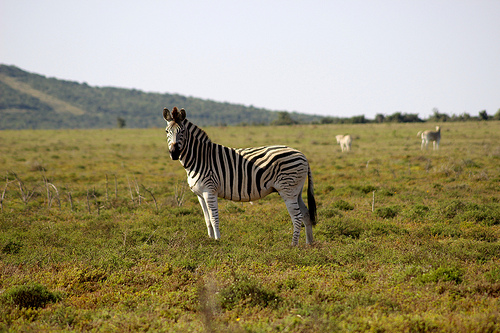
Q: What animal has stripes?
A: Zebra.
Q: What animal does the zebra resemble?
A: Horse.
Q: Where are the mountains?
A: Behind the zebra.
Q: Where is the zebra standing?
A: In the field.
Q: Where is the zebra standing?
A: In a field.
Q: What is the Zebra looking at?
A: The camera.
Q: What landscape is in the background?
A: A hill.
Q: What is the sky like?
A: Clear.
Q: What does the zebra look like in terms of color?
A: Black and white.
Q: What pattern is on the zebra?
A: Stripes.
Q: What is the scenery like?
A: Grassy Field.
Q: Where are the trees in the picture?
A: Behind the Zebra.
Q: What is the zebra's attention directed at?
A: The camera.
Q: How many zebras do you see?
A: Three.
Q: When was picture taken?
A: Daytime.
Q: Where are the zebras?
A: Field.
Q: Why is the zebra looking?
A: Photo.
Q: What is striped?
A: Zebras.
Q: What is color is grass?
A: Green.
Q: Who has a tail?
A: Zebras.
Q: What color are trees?
A: Green.